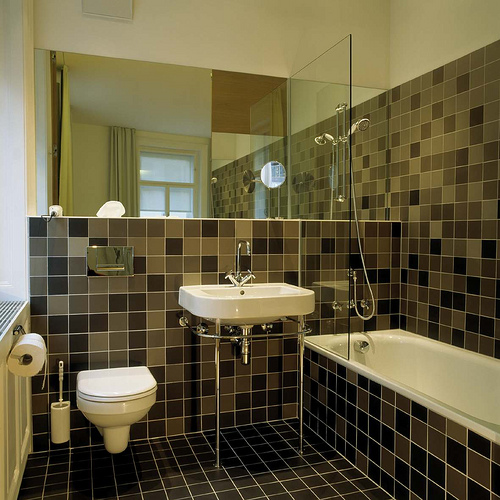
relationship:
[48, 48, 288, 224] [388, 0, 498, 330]
mirror on wall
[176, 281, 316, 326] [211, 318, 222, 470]
sink has leg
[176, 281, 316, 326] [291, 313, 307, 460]
sink has leg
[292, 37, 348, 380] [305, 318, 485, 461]
panel on side of bathtub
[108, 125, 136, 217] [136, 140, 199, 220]
curtain on window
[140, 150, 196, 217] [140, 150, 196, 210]
blinds with blinds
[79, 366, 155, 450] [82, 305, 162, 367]
toilet doesnt have tank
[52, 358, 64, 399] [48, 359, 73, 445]
handle of brush